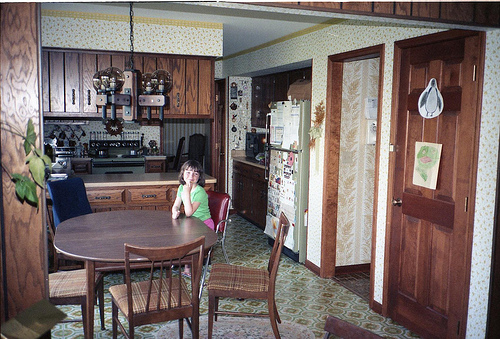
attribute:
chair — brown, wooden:
[206, 212, 296, 338]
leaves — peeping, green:
[23, 120, 38, 157]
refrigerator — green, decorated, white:
[261, 99, 313, 266]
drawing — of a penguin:
[417, 77, 446, 124]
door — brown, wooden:
[383, 32, 486, 338]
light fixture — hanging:
[90, 3, 176, 125]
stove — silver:
[89, 136, 148, 180]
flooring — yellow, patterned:
[46, 212, 424, 339]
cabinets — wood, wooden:
[39, 46, 217, 121]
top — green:
[176, 184, 212, 221]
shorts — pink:
[200, 217, 216, 234]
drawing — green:
[411, 139, 443, 193]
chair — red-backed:
[200, 191, 233, 300]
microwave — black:
[244, 131, 269, 157]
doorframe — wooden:
[318, 40, 386, 308]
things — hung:
[306, 99, 324, 172]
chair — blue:
[46, 172, 93, 229]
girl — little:
[163, 160, 219, 232]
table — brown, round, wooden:
[55, 206, 224, 270]